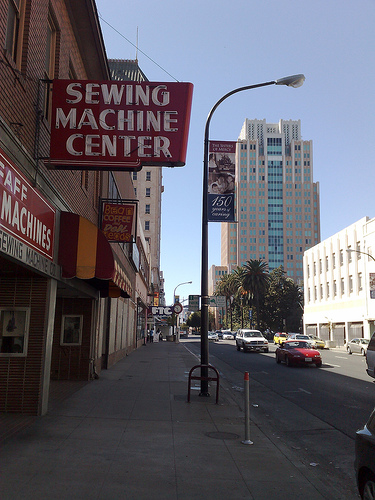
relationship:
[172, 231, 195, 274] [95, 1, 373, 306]
clouds in blue sky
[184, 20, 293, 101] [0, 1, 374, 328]
clouds in sky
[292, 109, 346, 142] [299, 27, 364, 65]
clouds in sky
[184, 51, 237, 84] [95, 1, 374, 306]
clouds in blue sky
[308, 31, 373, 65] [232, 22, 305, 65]
clouds in sky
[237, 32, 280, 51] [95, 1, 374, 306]
clouds in blue sky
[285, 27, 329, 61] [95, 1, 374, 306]
clouds in blue sky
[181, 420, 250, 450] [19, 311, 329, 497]
manhole on sidewalk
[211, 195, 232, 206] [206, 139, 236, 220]
150 on banner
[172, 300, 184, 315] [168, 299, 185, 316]
clock with face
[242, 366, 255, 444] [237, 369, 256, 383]
pole with top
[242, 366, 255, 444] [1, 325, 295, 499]
pole on sidewalk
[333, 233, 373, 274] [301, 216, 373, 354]
lamp in front of building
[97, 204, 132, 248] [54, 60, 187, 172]
coffee on sign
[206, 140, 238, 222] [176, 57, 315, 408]
banner on post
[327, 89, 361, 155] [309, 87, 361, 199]
clouds in sky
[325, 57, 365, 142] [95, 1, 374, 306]
clouds in blue sky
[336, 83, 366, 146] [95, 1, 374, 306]
clouds in blue sky